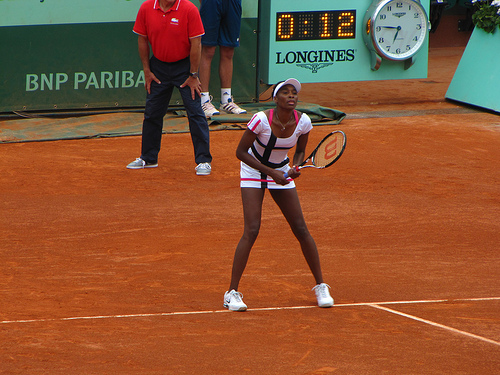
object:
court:
[0, 140, 499, 373]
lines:
[0, 296, 498, 323]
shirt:
[131, 0, 206, 63]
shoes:
[221, 290, 249, 313]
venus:
[220, 78, 335, 313]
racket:
[282, 130, 347, 178]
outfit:
[234, 107, 314, 190]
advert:
[268, 38, 429, 84]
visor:
[271, 77, 303, 94]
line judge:
[124, 0, 214, 177]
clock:
[362, 0, 431, 71]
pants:
[139, 54, 211, 165]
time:
[273, 9, 356, 44]